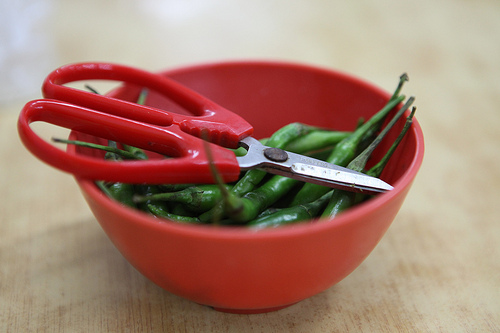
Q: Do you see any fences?
A: No, there are no fences.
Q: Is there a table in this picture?
A: Yes, there is a table.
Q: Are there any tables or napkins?
A: Yes, there is a table.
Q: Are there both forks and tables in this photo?
A: No, there is a table but no forks.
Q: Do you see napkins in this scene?
A: No, there are no napkins.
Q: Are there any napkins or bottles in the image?
A: No, there are no napkins or bottles.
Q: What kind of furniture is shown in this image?
A: The furniture is a table.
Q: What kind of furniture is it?
A: The piece of furniture is a table.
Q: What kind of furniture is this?
A: This is a table.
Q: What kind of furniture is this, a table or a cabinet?
A: This is a table.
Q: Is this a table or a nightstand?
A: This is a table.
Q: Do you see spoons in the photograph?
A: No, there are no spoons.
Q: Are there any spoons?
A: No, there are no spoons.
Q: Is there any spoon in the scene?
A: No, there are no spoons.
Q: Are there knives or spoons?
A: No, there are no spoons or knives.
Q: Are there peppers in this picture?
A: Yes, there is a pepper.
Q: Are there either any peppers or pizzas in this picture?
A: Yes, there is a pepper.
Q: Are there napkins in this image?
A: No, there are no napkins.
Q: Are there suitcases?
A: No, there are no suitcases.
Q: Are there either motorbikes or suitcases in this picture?
A: No, there are no suitcases or motorbikes.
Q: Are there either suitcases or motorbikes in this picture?
A: No, there are no suitcases or motorbikes.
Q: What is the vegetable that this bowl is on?
A: The vegetable is a pepper.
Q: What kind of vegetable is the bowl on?
A: The bowl is on the pepper.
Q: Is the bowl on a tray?
A: No, the bowl is on a pepper.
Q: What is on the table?
A: The bowl is on the table.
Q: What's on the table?
A: The bowl is on the table.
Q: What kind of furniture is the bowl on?
A: The bowl is on the table.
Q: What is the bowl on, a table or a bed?
A: The bowl is on a table.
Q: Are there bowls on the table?
A: Yes, there is a bowl on the table.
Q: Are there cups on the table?
A: No, there is a bowl on the table.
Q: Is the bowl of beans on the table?
A: Yes, the bowl is on the table.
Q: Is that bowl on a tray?
A: No, the bowl is on the table.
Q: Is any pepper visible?
A: Yes, there is a pepper.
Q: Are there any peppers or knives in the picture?
A: Yes, there is a pepper.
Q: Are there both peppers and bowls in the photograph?
A: Yes, there are both a pepper and a bowl.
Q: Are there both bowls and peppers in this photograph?
A: Yes, there are both a pepper and a bowl.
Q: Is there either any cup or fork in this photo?
A: No, there are no forks or cups.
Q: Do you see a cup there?
A: No, there are no cups.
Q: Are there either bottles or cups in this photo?
A: No, there are no cups or bottles.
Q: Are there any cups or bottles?
A: No, there are no cups or bottles.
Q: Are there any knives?
A: No, there are no knives.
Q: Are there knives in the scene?
A: No, there are no knives.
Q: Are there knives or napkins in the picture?
A: No, there are no knives or napkins.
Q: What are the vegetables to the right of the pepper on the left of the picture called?
A: The vegetables are beans.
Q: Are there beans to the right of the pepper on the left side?
A: Yes, there are beans to the right of the pepper.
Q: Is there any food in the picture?
A: Yes, there is food.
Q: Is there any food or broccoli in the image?
A: Yes, there is food.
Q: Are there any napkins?
A: No, there are no napkins.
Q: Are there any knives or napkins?
A: No, there are no napkins or knives.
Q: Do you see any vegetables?
A: Yes, there are vegetables.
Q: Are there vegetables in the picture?
A: Yes, there are vegetables.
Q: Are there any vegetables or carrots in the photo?
A: Yes, there are vegetables.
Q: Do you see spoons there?
A: No, there are no spoons.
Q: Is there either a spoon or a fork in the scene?
A: No, there are no spoons or forks.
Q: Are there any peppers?
A: Yes, there is a pepper.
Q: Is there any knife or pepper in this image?
A: Yes, there is a pepper.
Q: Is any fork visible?
A: No, there are no forks.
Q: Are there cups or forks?
A: No, there are no forks or cups.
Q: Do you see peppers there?
A: Yes, there is a pepper.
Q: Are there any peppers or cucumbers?
A: Yes, there is a pepper.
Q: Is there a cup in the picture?
A: No, there are no cups.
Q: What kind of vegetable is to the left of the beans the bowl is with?
A: The vegetable is a pepper.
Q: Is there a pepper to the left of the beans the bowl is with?
A: Yes, there is a pepper to the left of the beans.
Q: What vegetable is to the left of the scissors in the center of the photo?
A: The vegetable is a pepper.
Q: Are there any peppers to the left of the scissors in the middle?
A: Yes, there is a pepper to the left of the scissors.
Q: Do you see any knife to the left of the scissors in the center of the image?
A: No, there is a pepper to the left of the scissors.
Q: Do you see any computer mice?
A: No, there are no computer mice.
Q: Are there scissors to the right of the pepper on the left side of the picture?
A: Yes, there are scissors to the right of the pepper.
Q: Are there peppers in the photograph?
A: Yes, there is a pepper.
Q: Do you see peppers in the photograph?
A: Yes, there is a pepper.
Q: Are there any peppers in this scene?
A: Yes, there is a pepper.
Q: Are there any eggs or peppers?
A: Yes, there is a pepper.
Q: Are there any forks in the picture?
A: No, there are no forks.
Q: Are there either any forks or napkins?
A: No, there are no forks or napkins.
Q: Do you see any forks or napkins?
A: No, there are no forks or napkins.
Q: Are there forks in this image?
A: No, there are no forks.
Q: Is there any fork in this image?
A: No, there are no forks.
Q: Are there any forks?
A: No, there are no forks.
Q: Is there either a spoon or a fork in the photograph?
A: No, there are no forks or spoons.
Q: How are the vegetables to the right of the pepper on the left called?
A: The vegetables are beans.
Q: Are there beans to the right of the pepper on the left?
A: Yes, there are beans to the right of the pepper.